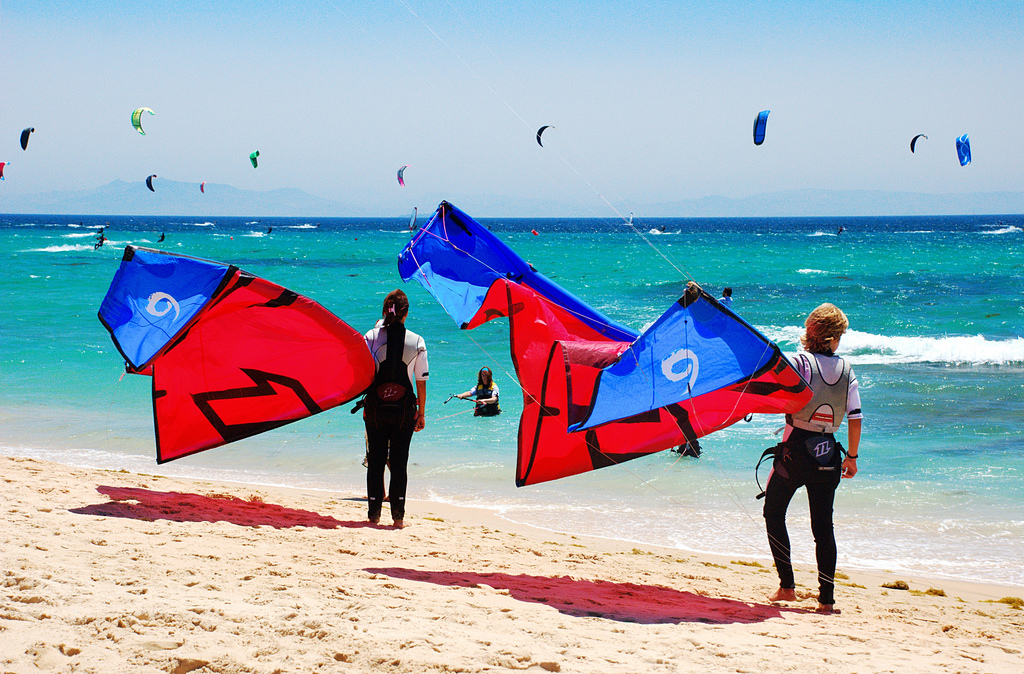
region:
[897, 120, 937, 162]
Kite in the sky over the ocean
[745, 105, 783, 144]
Kite in the sky over the ocean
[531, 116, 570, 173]
Kite in the sky over the ocean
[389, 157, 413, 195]
Kite in the sky over the ocean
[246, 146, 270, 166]
Kite in the sky over the ocean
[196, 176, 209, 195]
Kite in the sky over the ocean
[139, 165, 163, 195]
Kite in the sky over the ocean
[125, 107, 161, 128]
Kite in the sky over the ocean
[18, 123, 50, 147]
Kite in the sky over the ocean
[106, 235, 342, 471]
red and blue kite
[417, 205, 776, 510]
large red and blue kite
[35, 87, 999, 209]
kites in the air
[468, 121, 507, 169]
white clouds in blue sky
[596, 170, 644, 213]
white clouds in blue sky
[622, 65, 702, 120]
white clouds in blue sky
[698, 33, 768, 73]
white clouds in blue sky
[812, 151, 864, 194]
white clouds in blue sky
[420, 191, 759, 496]
red and blue kite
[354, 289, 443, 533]
young woman wearing wet suit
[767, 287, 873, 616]
young woman wearing wet suit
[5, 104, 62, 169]
large kite in the sky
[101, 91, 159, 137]
large kite in the sky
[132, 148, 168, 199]
large kite in the sky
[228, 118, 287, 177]
large kite in the sky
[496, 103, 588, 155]
large kite in the sky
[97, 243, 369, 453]
blue and red kite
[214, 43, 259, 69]
white clouds in blue sky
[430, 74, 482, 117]
white clouds in blue sky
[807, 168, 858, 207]
white clouds in blue sky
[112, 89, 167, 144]
large kite in the air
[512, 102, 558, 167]
large kite in the air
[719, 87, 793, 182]
large kite in the air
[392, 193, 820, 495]
one of many sails for parasailing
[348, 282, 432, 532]
woman standing on beach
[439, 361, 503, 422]
woman in water with sail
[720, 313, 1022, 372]
waves of water splashing toward beach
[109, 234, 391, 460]
the woman is holding a kite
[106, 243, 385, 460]
the kite is blue and red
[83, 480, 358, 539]
a shadow is on the ground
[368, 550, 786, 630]
a shadow is on the ground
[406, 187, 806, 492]
the kite is blue and red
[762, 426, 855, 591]
the person is wearing long pants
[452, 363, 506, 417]
the woman is in the water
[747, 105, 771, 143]
the kite is in the air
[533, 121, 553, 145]
the kite is in the air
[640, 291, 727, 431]
number on kite is white in color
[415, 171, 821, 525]
kit is red and blue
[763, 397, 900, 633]
person is wearing pants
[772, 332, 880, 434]
person is wearing shirt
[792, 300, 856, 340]
person has hair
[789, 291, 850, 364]
hair is blonde in color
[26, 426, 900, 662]
sand is on the beach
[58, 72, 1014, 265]
kites in the air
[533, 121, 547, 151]
kite is flying outside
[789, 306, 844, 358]
the hair of a man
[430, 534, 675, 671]
the shadow of a kite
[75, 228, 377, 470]
red and blue kite